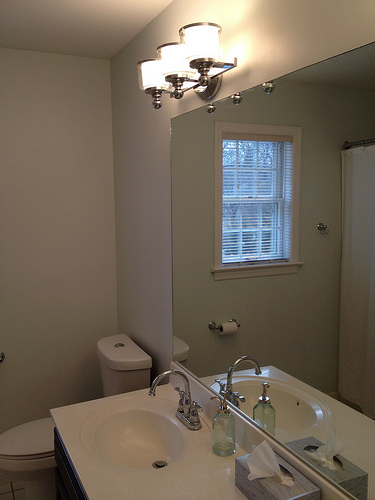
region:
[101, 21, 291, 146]
bathroom lights are on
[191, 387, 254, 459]
green bottle on sink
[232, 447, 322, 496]
box of tissues on sink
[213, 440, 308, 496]
tissue box is gray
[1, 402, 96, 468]
toilet seat and cover are down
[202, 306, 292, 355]
reflection of toilet paper in mirror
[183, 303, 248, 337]
toilet paper is on wall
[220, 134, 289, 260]
mini blinds in window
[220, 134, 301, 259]
mini blinds are open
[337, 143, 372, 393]
shower curtain is white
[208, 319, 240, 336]
the toilet paper holder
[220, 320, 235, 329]
the roll of toilet paper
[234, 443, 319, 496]
the gray kleenex box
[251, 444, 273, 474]
the piece of kleenex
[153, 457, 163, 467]
the silver sink drain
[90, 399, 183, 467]
the white bathroom sink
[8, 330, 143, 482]
the large white toilet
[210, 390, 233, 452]
the glass soap dispenser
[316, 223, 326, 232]
the silver wall hook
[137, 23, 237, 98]
the bathroom light fixture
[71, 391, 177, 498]
the sink is white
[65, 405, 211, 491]
the sink is clean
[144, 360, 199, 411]
the faucet is silver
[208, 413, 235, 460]
the container is empty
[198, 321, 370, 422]
there is reflection in the mirror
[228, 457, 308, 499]
the container is grey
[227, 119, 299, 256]
the blinds are open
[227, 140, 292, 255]
it is daylight outside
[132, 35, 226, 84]
the lights are on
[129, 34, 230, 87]
there are three lights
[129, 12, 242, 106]
A light fixture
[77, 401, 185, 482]
A white porcelin sink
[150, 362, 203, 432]
A silver water faucet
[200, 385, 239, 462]
An almost empty soap dispensor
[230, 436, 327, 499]
An open box of tissues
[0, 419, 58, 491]
The seat and bowl of a toilet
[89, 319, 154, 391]
A toilet tank with a push button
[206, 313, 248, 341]
The reflection of a roll of toilet paper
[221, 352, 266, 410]
The reflection of a faucet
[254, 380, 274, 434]
The reflection of a soap dispensor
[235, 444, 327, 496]
grey tissue box on sink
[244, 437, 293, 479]
tissue hanging from tissue box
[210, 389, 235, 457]
glass soap pump on sink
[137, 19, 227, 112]
lights affixed to wall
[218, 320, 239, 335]
tissue roll affixed to wall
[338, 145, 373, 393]
shower curtain hanging on rod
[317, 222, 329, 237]
metal towel hook on wall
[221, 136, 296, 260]
opened mini blinds on window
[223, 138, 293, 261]
closed window in restroom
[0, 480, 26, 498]
white tile on restroom floor